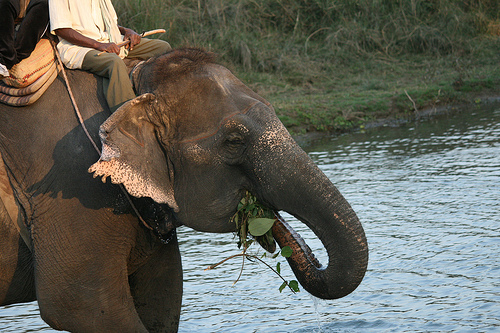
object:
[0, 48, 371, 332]
elephant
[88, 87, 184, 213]
ear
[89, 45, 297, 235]
head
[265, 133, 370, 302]
trunk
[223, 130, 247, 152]
eye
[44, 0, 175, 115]
man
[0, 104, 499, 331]
water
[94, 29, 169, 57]
stick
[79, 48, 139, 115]
right leg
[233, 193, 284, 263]
weeds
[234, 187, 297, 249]
mouth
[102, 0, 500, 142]
shore